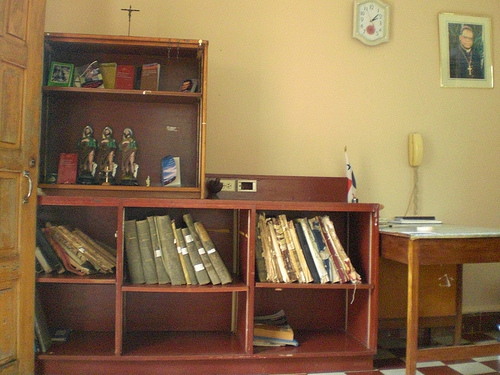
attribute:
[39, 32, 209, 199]
shelf — wooden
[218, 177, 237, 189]
outlet — white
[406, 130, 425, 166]
phone — yellow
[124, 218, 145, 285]
book — gray, old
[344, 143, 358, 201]
flag — white, blue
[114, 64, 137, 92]
book — red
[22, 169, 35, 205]
handle — metal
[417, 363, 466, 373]
floor tile — red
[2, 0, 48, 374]
door — wooden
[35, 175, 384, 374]
shelf — red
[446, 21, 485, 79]
photo — framed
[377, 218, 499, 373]
desk — small, wooden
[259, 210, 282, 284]
binding — worn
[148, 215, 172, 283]
book — brown